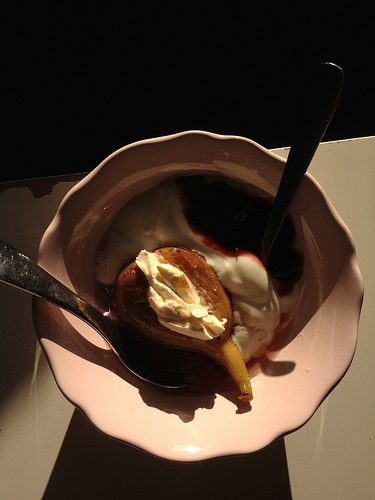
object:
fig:
[114, 245, 255, 404]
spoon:
[0, 243, 199, 391]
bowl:
[32, 128, 364, 464]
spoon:
[258, 62, 344, 270]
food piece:
[188, 305, 210, 319]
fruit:
[95, 180, 281, 359]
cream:
[133, 247, 227, 342]